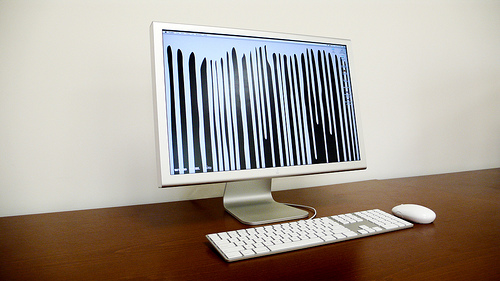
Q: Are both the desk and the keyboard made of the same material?
A: No, the desk is made of wood and the keyboard is made of metal.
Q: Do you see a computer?
A: Yes, there is a computer.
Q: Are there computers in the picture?
A: Yes, there is a computer.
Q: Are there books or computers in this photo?
A: Yes, there is a computer.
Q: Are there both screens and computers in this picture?
A: Yes, there are both a computer and a screen.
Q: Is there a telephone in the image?
A: No, there are no phones.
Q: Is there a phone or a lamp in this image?
A: No, there are no phones or lamps.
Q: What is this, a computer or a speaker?
A: This is a computer.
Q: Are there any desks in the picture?
A: Yes, there is a desk.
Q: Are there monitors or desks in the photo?
A: Yes, there is a desk.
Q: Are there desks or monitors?
A: Yes, there is a desk.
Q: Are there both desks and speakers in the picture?
A: No, there is a desk but no speakers.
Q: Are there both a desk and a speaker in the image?
A: No, there is a desk but no speakers.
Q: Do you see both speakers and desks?
A: No, there is a desk but no speakers.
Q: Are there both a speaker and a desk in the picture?
A: No, there is a desk but no speakers.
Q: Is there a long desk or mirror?
A: Yes, there is a long desk.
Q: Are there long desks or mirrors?
A: Yes, there is a long desk.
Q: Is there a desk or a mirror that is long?
A: Yes, the desk is long.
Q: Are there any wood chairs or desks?
A: Yes, there is a wood desk.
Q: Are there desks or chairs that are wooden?
A: Yes, the desk is wooden.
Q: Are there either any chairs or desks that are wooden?
A: Yes, the desk is wooden.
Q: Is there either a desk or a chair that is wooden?
A: Yes, the desk is wooden.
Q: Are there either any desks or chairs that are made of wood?
A: Yes, the desk is made of wood.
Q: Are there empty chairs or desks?
A: Yes, there is an empty desk.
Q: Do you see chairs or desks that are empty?
A: Yes, the desk is empty.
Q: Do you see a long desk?
A: Yes, there is a long desk.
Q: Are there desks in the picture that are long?
A: Yes, there is a desk that is long.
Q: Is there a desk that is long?
A: Yes, there is a desk that is long.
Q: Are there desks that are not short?
A: Yes, there is a long desk.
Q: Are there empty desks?
A: Yes, there is an empty desk.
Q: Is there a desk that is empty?
A: Yes, there is a desk that is empty.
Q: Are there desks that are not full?
A: Yes, there is a empty desk.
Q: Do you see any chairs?
A: No, there are no chairs.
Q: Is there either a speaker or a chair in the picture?
A: No, there are no chairs or speakers.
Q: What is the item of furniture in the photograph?
A: The piece of furniture is a desk.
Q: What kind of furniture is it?
A: The piece of furniture is a desk.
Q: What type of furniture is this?
A: This is a desk.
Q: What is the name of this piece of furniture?
A: This is a desk.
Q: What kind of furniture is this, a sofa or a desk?
A: This is a desk.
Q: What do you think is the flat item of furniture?
A: The piece of furniture is a desk.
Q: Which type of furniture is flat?
A: The furniture is a desk.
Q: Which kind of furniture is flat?
A: The furniture is a desk.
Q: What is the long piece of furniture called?
A: The piece of furniture is a desk.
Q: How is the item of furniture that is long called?
A: The piece of furniture is a desk.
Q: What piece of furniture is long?
A: The piece of furniture is a desk.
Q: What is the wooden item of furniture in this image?
A: The piece of furniture is a desk.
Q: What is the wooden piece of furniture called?
A: The piece of furniture is a desk.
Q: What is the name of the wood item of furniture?
A: The piece of furniture is a desk.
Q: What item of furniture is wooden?
A: The piece of furniture is a desk.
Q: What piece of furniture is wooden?
A: The piece of furniture is a desk.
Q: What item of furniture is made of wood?
A: The piece of furniture is a desk.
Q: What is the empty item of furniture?
A: The piece of furniture is a desk.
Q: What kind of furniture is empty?
A: The furniture is a desk.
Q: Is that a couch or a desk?
A: That is a desk.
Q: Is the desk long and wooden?
A: Yes, the desk is long and wooden.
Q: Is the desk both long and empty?
A: Yes, the desk is long and empty.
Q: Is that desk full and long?
A: No, the desk is long but empty.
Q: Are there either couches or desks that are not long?
A: No, there is a desk but it is long.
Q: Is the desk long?
A: Yes, the desk is long.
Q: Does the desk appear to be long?
A: Yes, the desk is long.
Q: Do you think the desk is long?
A: Yes, the desk is long.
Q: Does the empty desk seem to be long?
A: Yes, the desk is long.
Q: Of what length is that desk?
A: The desk is long.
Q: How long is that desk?
A: The desk is long.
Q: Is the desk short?
A: No, the desk is long.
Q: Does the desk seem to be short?
A: No, the desk is long.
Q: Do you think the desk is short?
A: No, the desk is long.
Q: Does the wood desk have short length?
A: No, the desk is long.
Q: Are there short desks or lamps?
A: No, there is a desk but it is long.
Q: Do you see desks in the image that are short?
A: No, there is a desk but it is long.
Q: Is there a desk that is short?
A: No, there is a desk but it is long.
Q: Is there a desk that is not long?
A: No, there is a desk but it is long.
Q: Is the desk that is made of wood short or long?
A: The desk is long.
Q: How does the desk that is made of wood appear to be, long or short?
A: The desk is long.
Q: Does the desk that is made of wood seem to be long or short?
A: The desk is long.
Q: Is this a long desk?
A: Yes, this is a long desk.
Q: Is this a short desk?
A: No, this is a long desk.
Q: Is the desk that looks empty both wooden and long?
A: Yes, the desk is wooden and long.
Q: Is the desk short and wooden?
A: No, the desk is wooden but long.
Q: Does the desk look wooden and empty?
A: Yes, the desk is wooden and empty.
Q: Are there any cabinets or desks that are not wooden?
A: No, there is a desk but it is wooden.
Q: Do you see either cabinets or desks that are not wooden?
A: No, there is a desk but it is wooden.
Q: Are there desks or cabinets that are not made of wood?
A: No, there is a desk but it is made of wood.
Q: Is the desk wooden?
A: Yes, the desk is wooden.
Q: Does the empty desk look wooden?
A: Yes, the desk is wooden.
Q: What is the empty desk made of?
A: The desk is made of wood.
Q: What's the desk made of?
A: The desk is made of wood.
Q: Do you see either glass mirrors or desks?
A: No, there is a desk but it is wooden.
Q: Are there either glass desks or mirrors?
A: No, there is a desk but it is wooden.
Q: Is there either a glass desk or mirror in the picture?
A: No, there is a desk but it is wooden.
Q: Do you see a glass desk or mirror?
A: No, there is a desk but it is wooden.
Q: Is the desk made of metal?
A: No, the desk is made of wood.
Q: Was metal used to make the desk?
A: No, the desk is made of wood.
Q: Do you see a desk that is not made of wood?
A: No, there is a desk but it is made of wood.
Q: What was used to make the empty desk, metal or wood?
A: The desk is made of wood.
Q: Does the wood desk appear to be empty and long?
A: Yes, the desk is empty and long.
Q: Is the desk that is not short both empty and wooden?
A: Yes, the desk is empty and wooden.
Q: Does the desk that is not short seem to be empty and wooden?
A: Yes, the desk is empty and wooden.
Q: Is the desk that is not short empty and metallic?
A: No, the desk is empty but wooden.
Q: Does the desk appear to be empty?
A: Yes, the desk is empty.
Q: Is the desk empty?
A: Yes, the desk is empty.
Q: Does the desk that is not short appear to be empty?
A: Yes, the desk is empty.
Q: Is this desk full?
A: No, the desk is empty.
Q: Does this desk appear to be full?
A: No, the desk is empty.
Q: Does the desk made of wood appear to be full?
A: No, the desk is empty.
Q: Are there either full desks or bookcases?
A: No, there is a desk but it is empty.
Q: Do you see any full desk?
A: No, there is a desk but it is empty.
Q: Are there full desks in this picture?
A: No, there is a desk but it is empty.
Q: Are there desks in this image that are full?
A: No, there is a desk but it is empty.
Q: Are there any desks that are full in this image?
A: No, there is a desk but it is empty.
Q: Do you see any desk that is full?
A: No, there is a desk but it is empty.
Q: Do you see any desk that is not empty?
A: No, there is a desk but it is empty.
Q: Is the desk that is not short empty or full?
A: The desk is empty.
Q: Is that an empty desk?
A: Yes, that is an empty desk.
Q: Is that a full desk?
A: No, that is an empty desk.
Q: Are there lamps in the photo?
A: No, there are no lamps.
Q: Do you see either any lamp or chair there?
A: No, there are no lamps or chairs.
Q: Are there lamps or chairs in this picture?
A: No, there are no lamps or chairs.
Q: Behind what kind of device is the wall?
A: The wall is behind the screen.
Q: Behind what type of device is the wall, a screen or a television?
A: The wall is behind a screen.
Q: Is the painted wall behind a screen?
A: Yes, the wall is behind a screen.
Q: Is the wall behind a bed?
A: No, the wall is behind a screen.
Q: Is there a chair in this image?
A: No, there are no chairs.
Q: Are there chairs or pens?
A: No, there are no chairs or pens.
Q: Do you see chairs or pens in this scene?
A: No, there are no chairs or pens.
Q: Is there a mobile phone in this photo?
A: No, there are no cell phones.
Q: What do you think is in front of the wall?
A: The screen is in front of the wall.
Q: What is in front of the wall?
A: The screen is in front of the wall.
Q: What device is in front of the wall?
A: The device is a screen.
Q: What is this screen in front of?
A: The screen is in front of the wall.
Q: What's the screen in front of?
A: The screen is in front of the wall.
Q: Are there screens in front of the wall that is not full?
A: Yes, there is a screen in front of the wall.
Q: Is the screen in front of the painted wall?
A: Yes, the screen is in front of the wall.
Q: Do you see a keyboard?
A: Yes, there is a keyboard.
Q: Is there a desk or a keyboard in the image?
A: Yes, there is a keyboard.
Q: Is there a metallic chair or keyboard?
A: Yes, there is a metal keyboard.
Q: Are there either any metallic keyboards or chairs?
A: Yes, there is a metal keyboard.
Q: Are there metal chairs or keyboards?
A: Yes, there is a metal keyboard.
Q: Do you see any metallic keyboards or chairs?
A: Yes, there is a metal keyboard.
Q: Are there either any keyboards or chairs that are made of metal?
A: Yes, the keyboard is made of metal.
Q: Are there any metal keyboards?
A: Yes, there is a metal keyboard.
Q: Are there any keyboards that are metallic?
A: Yes, there is a keyboard that is metallic.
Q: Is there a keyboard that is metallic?
A: Yes, there is a keyboard that is metallic.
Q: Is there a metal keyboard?
A: Yes, there is a keyboard that is made of metal.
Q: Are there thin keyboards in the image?
A: Yes, there is a thin keyboard.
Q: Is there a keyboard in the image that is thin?
A: Yes, there is a keyboard that is thin.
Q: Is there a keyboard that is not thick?
A: Yes, there is a thin keyboard.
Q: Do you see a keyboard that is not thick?
A: Yes, there is a thin keyboard.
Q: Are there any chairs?
A: No, there are no chairs.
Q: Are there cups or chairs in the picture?
A: No, there are no chairs or cups.